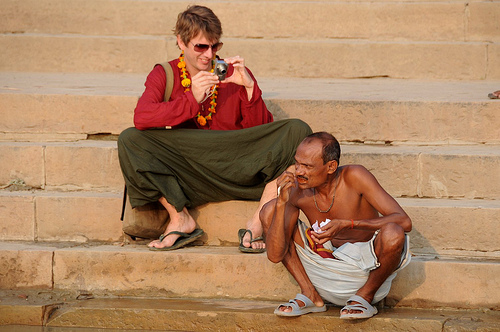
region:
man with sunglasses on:
[151, 18, 252, 80]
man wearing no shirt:
[272, 131, 400, 242]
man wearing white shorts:
[235, 194, 422, 295]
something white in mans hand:
[294, 211, 354, 261]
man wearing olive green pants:
[108, 118, 326, 186]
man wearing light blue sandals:
[262, 280, 383, 328]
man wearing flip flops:
[130, 207, 311, 264]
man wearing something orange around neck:
[177, 32, 239, 140]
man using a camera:
[164, 28, 249, 82]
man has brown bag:
[112, 38, 192, 252]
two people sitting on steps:
[99, 4, 441, 325]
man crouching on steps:
[254, 128, 415, 325]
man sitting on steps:
[109, 2, 313, 255]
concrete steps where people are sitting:
[21, 17, 107, 314]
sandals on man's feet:
[273, 288, 381, 322]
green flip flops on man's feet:
[144, 219, 271, 254]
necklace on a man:
[308, 188, 340, 218]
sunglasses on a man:
[177, 35, 232, 55]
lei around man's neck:
[167, 53, 192, 85]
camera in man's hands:
[210, 54, 232, 85]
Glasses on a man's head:
[193, 40, 224, 55]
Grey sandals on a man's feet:
[272, 286, 377, 321]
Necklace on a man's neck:
[308, 185, 338, 214]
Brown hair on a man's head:
[172, 10, 222, 40]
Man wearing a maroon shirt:
[133, 62, 271, 124]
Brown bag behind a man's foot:
[118, 198, 177, 242]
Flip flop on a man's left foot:
[236, 225, 265, 250]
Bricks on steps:
[4, 140, 120, 242]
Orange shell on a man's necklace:
[199, 115, 205, 125]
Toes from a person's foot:
[487, 81, 499, 97]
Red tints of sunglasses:
[195, 39, 224, 52]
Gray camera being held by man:
[211, 60, 231, 82]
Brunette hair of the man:
[187, 10, 210, 28]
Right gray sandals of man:
[277, 300, 320, 320]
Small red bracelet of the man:
[348, 216, 355, 231]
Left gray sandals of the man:
[342, 294, 375, 330]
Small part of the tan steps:
[10, 204, 77, 244]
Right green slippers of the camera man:
[162, 229, 199, 251]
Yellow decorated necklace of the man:
[173, 62, 193, 88]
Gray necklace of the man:
[310, 196, 339, 217]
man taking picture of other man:
[109, 2, 292, 235]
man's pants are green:
[99, 91, 330, 212]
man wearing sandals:
[136, 206, 337, 286]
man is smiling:
[153, 0, 251, 78]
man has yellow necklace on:
[160, 36, 237, 147]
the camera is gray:
[205, 50, 235, 88]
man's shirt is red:
[135, 47, 300, 139]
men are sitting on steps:
[95, 3, 488, 330]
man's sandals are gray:
[267, 282, 404, 329]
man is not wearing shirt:
[266, 136, 400, 240]